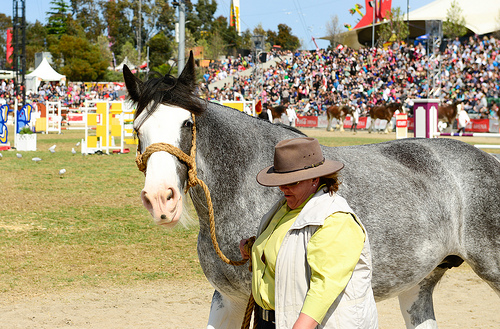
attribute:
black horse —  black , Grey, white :
[109, 56, 473, 295]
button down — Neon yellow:
[240, 213, 384, 323]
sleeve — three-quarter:
[299, 212, 361, 322]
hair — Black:
[117, 54, 204, 109]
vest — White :
[238, 182, 380, 324]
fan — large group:
[460, 65, 475, 87]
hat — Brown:
[251, 120, 353, 185]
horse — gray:
[99, 49, 433, 299]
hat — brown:
[252, 134, 346, 189]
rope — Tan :
[132, 112, 254, 273]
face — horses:
[133, 99, 200, 226]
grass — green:
[3, 176, 180, 288]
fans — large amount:
[326, 91, 366, 107]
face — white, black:
[131, 113, 191, 222]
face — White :
[134, 103, 193, 225]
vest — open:
[267, 196, 410, 318]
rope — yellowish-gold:
[138, 145, 186, 162]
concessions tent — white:
[19, 54, 66, 94]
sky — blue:
[242, 0, 309, 23]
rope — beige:
[137, 120, 237, 275]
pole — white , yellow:
[117, 95, 136, 154]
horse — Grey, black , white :
[132, 84, 286, 261]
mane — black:
[145, 69, 172, 98]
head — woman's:
[253, 164, 345, 206]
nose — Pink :
[141, 185, 175, 227]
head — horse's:
[123, 53, 219, 226]